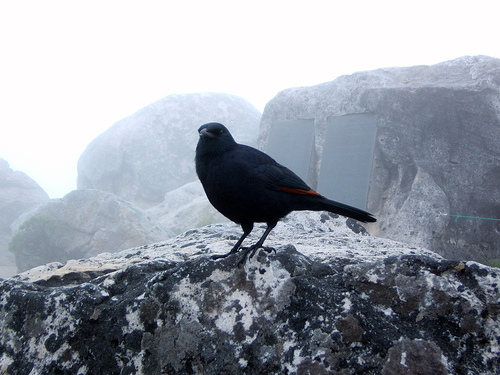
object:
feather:
[275, 186, 322, 197]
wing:
[243, 147, 322, 195]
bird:
[194, 122, 378, 259]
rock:
[2, 208, 498, 374]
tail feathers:
[299, 195, 375, 227]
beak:
[199, 129, 209, 138]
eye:
[217, 130, 223, 135]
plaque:
[264, 117, 318, 193]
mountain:
[250, 54, 499, 268]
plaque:
[318, 114, 375, 212]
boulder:
[8, 186, 172, 269]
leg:
[228, 229, 253, 254]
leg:
[255, 223, 278, 247]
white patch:
[122, 304, 146, 333]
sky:
[0, 0, 500, 202]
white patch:
[245, 257, 290, 299]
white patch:
[339, 296, 353, 315]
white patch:
[291, 346, 308, 366]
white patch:
[422, 268, 438, 309]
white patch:
[126, 349, 146, 374]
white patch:
[102, 275, 116, 291]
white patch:
[464, 259, 490, 270]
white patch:
[213, 307, 239, 335]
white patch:
[397, 352, 410, 369]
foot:
[240, 244, 266, 261]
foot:
[210, 253, 228, 262]